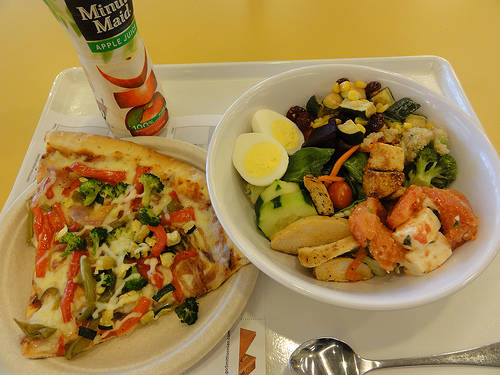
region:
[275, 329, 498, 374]
silver-plated teaspon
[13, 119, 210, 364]
slice of pizza topped with vegetables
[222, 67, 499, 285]
plate with various food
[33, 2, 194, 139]
bottle of apple juice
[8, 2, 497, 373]
tray full of food and drink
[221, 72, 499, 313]
plate of food that includes deviled eggs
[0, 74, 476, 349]
two plates full of food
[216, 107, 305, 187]
two deviled eggs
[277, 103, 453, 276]
various meats and vegetables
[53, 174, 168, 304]
toppings on a slice of pizza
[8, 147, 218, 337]
slice of pizza on plate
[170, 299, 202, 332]
broccoli floret on pizza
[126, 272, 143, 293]
broccoli floret on pizza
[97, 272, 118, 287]
broccoli floret on pizza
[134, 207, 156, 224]
broccoli floret on pizza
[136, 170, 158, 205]
broccoli floret on pizza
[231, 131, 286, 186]
half of boiled egg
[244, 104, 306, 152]
half of boiled egg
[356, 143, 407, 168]
crouton on top of salad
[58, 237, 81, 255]
broccoli floret on pizza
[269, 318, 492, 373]
the spoon is silver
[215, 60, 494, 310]
the food is in a bowl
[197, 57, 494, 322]
the bowl is white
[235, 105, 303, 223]
the hard boiled egg is next to the slices of cucumber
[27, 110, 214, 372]
the pizza is on a plate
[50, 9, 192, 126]
the apple juice is behind the pizza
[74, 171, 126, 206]
the broccoli is green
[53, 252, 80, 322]
the peppers are red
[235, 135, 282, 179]
the yolk is yellow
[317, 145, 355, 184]
the carrot is shredded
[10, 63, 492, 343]
two plates of food on white tray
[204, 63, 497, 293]
bowl of salad on white tray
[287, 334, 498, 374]
silver spoon on tray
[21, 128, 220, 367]
large slice of veggie pizza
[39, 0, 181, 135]
bottle of apple juice on tray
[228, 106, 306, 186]
eggs in a bowl of salad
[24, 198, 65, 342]
red and green peppers on pizza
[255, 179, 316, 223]
two slices of cucumbers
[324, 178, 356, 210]
one cherry tomato in bowl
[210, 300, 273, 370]
brown mark on paper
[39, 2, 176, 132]
Minute made apple juice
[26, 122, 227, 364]
Loaded vegetarian pizza slice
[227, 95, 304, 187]
Hard boiled egg halves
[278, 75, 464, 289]
Salad with many vegetables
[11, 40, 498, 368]
White serving tray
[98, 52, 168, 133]
Picture of apples on juice bottle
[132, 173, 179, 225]
Broccoli on the pizza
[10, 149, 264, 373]
Paper plate with pizza on it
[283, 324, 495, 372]
Silver spoon on tray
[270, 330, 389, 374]
Reflections of lights on tray and spoons